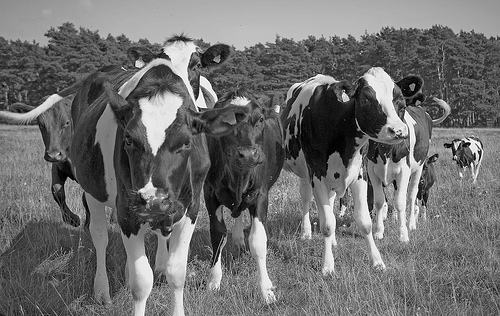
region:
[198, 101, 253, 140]
an ear of a cow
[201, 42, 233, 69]
an ear of a cow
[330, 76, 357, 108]
an ear of a cow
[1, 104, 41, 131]
tip of a cows tail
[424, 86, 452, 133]
the tail of a cow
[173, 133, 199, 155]
an eye of the cow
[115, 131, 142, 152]
an eye of the cow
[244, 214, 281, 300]
a leg of a cow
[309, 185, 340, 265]
a leg of a cow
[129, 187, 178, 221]
a nose of a cow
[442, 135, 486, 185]
a black and white cow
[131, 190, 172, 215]
nose of a cow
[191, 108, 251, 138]
ear of a cow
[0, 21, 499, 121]
tall trees behind cows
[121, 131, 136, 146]
right eye of cow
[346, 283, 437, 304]
grass on the ground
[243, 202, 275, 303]
left leg of cow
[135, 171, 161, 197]
white spot on cows nose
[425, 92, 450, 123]
tail of a cow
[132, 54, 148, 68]
white tag in cows ear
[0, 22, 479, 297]
a group of cows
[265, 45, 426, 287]
a two toned cow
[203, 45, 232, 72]
a plastic ear tag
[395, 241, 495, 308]
some long leaves of grass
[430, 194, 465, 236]
a few small wild flowers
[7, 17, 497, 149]
a forest in the background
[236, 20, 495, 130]
a row of trees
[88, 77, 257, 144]
a pair of ears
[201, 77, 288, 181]
a curious cow face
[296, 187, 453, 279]
a bunch of legs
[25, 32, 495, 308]
Eight cows posing for photo.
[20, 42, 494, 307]
Cows in the field gazing.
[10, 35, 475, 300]
Cows standing on grass.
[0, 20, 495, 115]
Trees behind the cows in the field.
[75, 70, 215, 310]
Cow posing for a photo.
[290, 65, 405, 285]
Cow posing for a photo in the field.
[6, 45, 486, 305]
Many cows moving together in a field.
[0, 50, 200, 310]
A cow with its tail up.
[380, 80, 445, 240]
A cow with its tail up.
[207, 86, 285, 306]
Cow in the field grazing.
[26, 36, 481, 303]
herd of cows in the grass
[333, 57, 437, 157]
cow head with black ears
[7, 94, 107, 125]
swinging tail of a cow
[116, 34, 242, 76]
tags on both ears of a cow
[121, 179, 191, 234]
shiny snout of a cow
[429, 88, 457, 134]
swinging white tail of a cow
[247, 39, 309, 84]
green pine trees behind a meadow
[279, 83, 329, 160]
black spots on a white cow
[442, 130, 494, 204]
one cow behind the herd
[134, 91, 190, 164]
triangular white shape on cow head